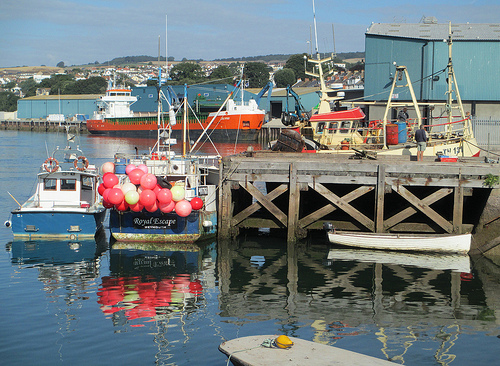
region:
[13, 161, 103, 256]
blue and white boat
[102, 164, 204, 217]
buoys hanging on boat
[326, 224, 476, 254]
white boat in water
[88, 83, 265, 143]
white and orange boat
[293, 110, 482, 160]
red and white boat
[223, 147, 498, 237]
grey wooden boat pier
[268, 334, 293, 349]
yellow bouy on boat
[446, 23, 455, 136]
tan mast on boat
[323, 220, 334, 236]
green engine on boat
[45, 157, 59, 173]
orange innertube on boat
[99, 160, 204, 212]
balloons on boat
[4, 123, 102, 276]
boat in the water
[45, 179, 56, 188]
window on boat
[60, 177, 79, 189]
window on boat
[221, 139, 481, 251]
wooden pier of water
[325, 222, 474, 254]
canoe in water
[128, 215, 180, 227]
name on the back of boat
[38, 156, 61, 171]
life preserver on boat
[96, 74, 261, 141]
boat in water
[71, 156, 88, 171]
life preserver on boat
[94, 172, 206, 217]
balloons on back of boat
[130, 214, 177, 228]
boat name "Royal Escape"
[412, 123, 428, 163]
person standing on dock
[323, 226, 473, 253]
small white boat next to dock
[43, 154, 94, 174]
two orange life preservers on blue boat on left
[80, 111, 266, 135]
large red boat in distance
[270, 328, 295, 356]
yellow cleat in foreground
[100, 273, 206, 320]
reflection of balloons in water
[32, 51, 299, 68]
line of trees in far distance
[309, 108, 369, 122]
red roof on pale yellow boat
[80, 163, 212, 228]
balloons back on boat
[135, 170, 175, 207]
the balloons are pink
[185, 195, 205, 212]
the balloon is red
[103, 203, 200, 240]
back of boat is blue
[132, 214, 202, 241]
the letters are white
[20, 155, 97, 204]
top of boat is white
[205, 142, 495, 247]
the dock is brown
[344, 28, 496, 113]
the building is blue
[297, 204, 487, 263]
white boat near the dock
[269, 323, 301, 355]
yellow object on boat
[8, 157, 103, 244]
A blue and white boat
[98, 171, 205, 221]
A bunch a balloons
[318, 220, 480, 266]
A white canoe on the water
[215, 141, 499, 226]
A brown old pier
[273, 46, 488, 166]
A large boat by the pier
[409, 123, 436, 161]
A man standing on the pier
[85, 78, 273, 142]
A large boat on the water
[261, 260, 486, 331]
Calm and clear water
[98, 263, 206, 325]
The reflection of the balloons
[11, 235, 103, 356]
The reflection of the blue and white boat